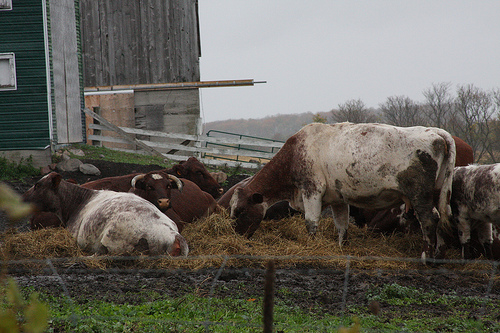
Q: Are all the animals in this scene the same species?
A: Yes, all the animals are cows.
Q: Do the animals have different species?
A: No, all the animals are cows.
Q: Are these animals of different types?
A: No, all the animals are cows.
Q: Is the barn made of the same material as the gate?
A: No, the barn is made of wood and the gate is made of metal.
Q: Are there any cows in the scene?
A: Yes, there is a cow.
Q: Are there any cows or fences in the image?
A: Yes, there is a cow.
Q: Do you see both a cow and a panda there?
A: No, there is a cow but no pandas.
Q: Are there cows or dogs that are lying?
A: Yes, the cow is lying.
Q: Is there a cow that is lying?
A: Yes, there is a cow that is lying.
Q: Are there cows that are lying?
A: Yes, there is a cow that is lying.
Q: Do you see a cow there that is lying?
A: Yes, there is a cow that is lying.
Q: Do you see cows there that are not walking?
A: Yes, there is a cow that is lying .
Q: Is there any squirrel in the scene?
A: No, there are no squirrels.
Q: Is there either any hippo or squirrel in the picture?
A: No, there are no squirrels or hippoes.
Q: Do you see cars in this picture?
A: No, there are no cars.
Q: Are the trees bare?
A: Yes, the trees are bare.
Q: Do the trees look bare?
A: Yes, the trees are bare.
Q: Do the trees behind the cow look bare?
A: Yes, the trees are bare.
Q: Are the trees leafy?
A: No, the trees are bare.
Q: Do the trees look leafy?
A: No, the trees are bare.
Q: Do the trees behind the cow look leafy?
A: No, the trees are bare.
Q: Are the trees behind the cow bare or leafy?
A: The trees are bare.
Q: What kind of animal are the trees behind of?
A: The trees are behind the cow.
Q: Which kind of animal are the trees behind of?
A: The trees are behind the cow.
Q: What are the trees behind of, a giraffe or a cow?
A: The trees are behind a cow.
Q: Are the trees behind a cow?
A: Yes, the trees are behind a cow.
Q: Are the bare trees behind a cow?
A: Yes, the trees are behind a cow.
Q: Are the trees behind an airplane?
A: No, the trees are behind a cow.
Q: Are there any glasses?
A: No, there are no glasses.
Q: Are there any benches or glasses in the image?
A: No, there are no glasses or benches.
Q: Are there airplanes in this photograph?
A: No, there are no airplanes.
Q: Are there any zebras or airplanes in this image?
A: No, there are no airplanes or zebras.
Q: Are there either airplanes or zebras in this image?
A: No, there are no airplanes or zebras.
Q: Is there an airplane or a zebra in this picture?
A: No, there are no airplanes or zebras.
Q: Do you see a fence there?
A: Yes, there is a fence.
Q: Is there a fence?
A: Yes, there is a fence.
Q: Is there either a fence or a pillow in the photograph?
A: Yes, there is a fence.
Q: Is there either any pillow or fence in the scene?
A: Yes, there is a fence.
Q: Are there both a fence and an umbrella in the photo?
A: No, there is a fence but no umbrellas.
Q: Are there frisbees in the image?
A: No, there are no frisbees.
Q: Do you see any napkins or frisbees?
A: No, there are no frisbees or napkins.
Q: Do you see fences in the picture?
A: Yes, there is a fence.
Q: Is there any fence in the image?
A: Yes, there is a fence.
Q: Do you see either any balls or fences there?
A: Yes, there is a fence.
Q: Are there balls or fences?
A: Yes, there is a fence.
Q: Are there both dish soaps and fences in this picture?
A: No, there is a fence but no dish soaps.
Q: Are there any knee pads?
A: No, there are no knee pads.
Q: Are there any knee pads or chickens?
A: No, there are no knee pads or chickens.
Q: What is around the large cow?
A: The fence is around the cow.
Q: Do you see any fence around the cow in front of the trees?
A: Yes, there is a fence around the cow.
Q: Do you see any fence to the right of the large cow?
A: No, the fence is to the left of the cow.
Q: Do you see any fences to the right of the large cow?
A: No, the fence is to the left of the cow.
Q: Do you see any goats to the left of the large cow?
A: No, there is a fence to the left of the cow.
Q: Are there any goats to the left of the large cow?
A: No, there is a fence to the left of the cow.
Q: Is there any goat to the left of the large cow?
A: No, there is a fence to the left of the cow.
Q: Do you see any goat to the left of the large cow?
A: No, there is a fence to the left of the cow.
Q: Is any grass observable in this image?
A: Yes, there is grass.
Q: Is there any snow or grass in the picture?
A: Yes, there is grass.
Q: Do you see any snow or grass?
A: Yes, there is grass.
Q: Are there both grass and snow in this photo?
A: No, there is grass but no snow.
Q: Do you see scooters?
A: No, there are no scooters.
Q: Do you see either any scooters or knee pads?
A: No, there are no scooters or knee pads.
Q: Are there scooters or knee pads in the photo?
A: No, there are no scooters or knee pads.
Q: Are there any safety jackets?
A: No, there are no safety jackets.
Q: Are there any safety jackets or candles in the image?
A: No, there are no safety jackets or candles.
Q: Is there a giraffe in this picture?
A: No, there are no giraffes.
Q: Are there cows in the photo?
A: Yes, there is a cow.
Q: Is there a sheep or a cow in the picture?
A: Yes, there is a cow.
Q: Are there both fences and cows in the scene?
A: Yes, there are both a cow and a fence.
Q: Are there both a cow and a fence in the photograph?
A: Yes, there are both a cow and a fence.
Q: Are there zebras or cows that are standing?
A: Yes, the cow is standing.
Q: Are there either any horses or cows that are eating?
A: Yes, the cow is eating.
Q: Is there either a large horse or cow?
A: Yes, there is a large cow.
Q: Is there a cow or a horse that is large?
A: Yes, the cow is large.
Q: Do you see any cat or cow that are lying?
A: Yes, the cow is lying.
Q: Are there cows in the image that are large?
A: Yes, there is a large cow.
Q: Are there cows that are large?
A: Yes, there is a cow that is large.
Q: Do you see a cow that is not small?
A: Yes, there is a large cow.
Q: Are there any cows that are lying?
A: Yes, there is a cow that is lying.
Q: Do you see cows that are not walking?
A: Yes, there is a cow that is lying .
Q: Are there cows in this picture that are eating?
A: Yes, there is a cow that is eating.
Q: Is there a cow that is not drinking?
A: Yes, there is a cow that is eating.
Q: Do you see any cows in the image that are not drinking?
A: Yes, there is a cow that is eating .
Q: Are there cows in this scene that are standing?
A: Yes, there is a cow that is standing.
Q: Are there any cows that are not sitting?
A: Yes, there is a cow that is standing.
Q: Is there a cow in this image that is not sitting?
A: Yes, there is a cow that is standing.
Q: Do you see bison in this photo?
A: No, there are no bison.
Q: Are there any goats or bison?
A: No, there are no bison or goats.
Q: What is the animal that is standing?
A: The animal is a cow.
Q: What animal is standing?
A: The animal is a cow.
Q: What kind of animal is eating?
A: The animal is a cow.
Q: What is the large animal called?
A: The animal is a cow.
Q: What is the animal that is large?
A: The animal is a cow.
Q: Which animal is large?
A: The animal is a cow.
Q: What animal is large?
A: The animal is a cow.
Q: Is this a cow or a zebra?
A: This is a cow.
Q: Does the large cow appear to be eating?
A: Yes, the cow is eating.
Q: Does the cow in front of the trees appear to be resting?
A: No, the cow is eating.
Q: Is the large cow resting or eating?
A: The cow is eating.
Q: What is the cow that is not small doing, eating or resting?
A: The cow is eating.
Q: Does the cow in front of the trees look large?
A: Yes, the cow is large.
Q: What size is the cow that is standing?
A: The cow is large.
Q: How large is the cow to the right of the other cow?
A: The cow is large.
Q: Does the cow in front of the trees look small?
A: No, the cow is large.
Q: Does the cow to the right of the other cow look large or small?
A: The cow is large.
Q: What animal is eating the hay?
A: The cow is eating the hay.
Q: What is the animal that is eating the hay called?
A: The animal is a cow.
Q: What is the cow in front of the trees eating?
A: The cow is eating hay.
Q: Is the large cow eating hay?
A: Yes, the cow is eating hay.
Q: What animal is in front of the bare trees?
A: The cow is in front of the trees.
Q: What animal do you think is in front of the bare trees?
A: The cow is in front of the trees.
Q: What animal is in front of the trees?
A: The cow is in front of the trees.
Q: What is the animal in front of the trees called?
A: The animal is a cow.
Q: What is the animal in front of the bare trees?
A: The animal is a cow.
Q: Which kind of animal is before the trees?
A: The animal is a cow.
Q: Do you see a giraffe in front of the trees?
A: No, there is a cow in front of the trees.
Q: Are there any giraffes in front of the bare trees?
A: No, there is a cow in front of the trees.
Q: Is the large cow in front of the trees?
A: Yes, the cow is in front of the trees.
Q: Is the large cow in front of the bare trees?
A: Yes, the cow is in front of the trees.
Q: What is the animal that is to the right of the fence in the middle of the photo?
A: The animal is a cow.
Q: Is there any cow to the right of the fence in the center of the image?
A: Yes, there is a cow to the right of the fence.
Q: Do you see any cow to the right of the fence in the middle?
A: Yes, there is a cow to the right of the fence.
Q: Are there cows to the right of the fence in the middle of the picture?
A: Yes, there is a cow to the right of the fence.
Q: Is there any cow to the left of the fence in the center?
A: No, the cow is to the right of the fence.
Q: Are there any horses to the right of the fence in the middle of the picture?
A: No, there is a cow to the right of the fence.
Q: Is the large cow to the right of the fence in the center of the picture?
A: Yes, the cow is to the right of the fence.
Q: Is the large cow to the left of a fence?
A: No, the cow is to the right of a fence.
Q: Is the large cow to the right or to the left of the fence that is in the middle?
A: The cow is to the right of the fence.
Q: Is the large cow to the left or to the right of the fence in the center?
A: The cow is to the right of the fence.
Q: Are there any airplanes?
A: No, there are no airplanes.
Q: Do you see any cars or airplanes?
A: No, there are no airplanes or cars.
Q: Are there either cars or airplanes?
A: No, there are no airplanes or cars.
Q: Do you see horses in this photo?
A: No, there are no horses.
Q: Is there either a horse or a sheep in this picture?
A: No, there are no horses or sheep.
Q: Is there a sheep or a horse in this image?
A: No, there are no horses or sheep.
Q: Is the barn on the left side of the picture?
A: Yes, the barn is on the left of the image.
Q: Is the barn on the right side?
A: No, the barn is on the left of the image.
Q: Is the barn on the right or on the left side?
A: The barn is on the left of the image.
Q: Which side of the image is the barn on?
A: The barn is on the left of the image.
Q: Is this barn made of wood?
A: Yes, the barn is made of wood.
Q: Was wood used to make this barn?
A: Yes, the barn is made of wood.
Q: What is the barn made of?
A: The barn is made of wood.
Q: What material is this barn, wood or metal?
A: The barn is made of wood.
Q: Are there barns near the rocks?
A: Yes, there is a barn near the rocks.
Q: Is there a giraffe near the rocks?
A: No, there is a barn near the rocks.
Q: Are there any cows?
A: Yes, there is a cow.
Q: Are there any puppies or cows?
A: Yes, there is a cow.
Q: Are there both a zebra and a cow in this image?
A: No, there is a cow but no zebras.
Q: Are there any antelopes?
A: No, there are no antelopes.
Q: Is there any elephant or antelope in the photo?
A: No, there are no antelopes or elephants.